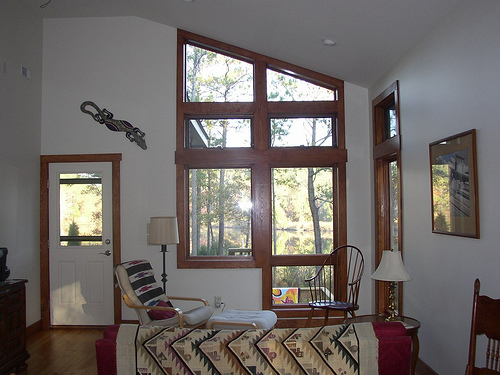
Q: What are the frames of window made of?
A: Wood.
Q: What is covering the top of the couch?
A: A blanket.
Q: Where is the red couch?
A: In the living room.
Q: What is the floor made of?
A: Wood.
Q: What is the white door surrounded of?
A: A wooden frame.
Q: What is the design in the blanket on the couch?
A: Native American.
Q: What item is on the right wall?
A: A picture.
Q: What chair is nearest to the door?
A: The chair with the woven blanket.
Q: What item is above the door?
A: A decoration.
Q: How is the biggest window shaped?
A: Oddly.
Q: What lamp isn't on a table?
A: The one near the door.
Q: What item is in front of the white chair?
A: A foot rest.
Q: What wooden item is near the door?
A: A dresser.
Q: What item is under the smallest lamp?
A: A table.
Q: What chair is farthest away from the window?
A: The one on the far right of the photo.